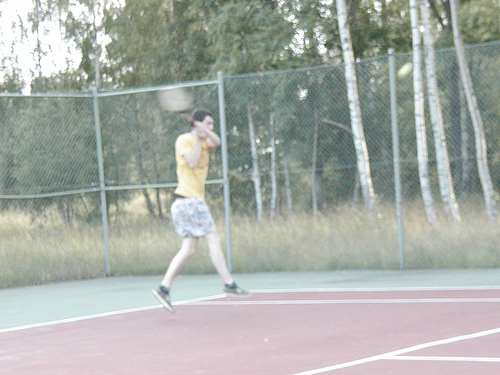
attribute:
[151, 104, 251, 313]
man — playing, swinging, airborne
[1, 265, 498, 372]
court — clay, green, red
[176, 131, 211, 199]
shirt — yellow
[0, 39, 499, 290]
fence — chainlink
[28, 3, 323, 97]
tree — green, fence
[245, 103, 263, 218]
trunk — small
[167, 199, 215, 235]
shorts — falling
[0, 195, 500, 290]
grass — tall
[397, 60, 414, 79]
ball — blurry, moving, green